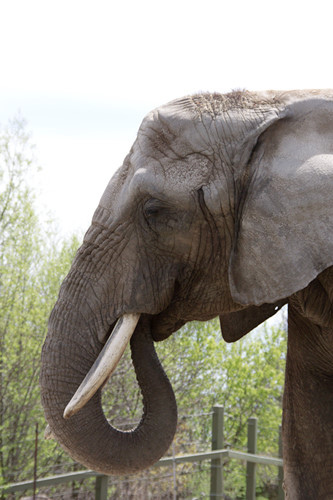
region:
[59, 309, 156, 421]
White tusk of elephant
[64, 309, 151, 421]
Grey and white tusk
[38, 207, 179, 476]
Curved trunk of elephant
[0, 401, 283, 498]
Steel rope gate in the background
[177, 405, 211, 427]
Steel rope of gate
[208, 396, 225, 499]
Green post of gate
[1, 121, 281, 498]
Green trees behind elephant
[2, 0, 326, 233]
Sky in the color of white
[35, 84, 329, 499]
Large grey elephant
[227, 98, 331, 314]
Large ear of elephant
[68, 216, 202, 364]
elephant's skin is wrinkled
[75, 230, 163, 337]
elephant's skin is wrinkled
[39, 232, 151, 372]
elephant's skin is wrinkled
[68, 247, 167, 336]
a gray, wrinkled skin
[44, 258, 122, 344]
a gray, wrinkled skin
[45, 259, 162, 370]
a gray, wrinkled skin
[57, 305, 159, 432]
long white tusk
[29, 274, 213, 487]
tusk on the side of the trunk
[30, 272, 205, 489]
trunk is curled up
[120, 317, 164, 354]
tip of the trunk is in the mouth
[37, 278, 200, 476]
lines on the trunk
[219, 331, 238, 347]
rounded tip of the ear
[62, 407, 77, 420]
tip of the tusk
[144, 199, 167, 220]
eye on the side of the head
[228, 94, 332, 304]
large ear on the side of the head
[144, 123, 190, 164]
lines on the skin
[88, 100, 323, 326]
an elephant eating a meal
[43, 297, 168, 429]
the elephant's tusk is white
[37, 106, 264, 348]
this elephant is old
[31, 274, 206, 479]
the elephant's trunk is curved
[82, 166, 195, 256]
the elephant's eyes look tired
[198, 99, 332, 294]
the ear on the elephant is big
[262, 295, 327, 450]
a part of the elephant's body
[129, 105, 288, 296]
the elephant is gray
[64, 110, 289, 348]
a big elephant eat food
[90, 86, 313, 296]
this elephant has wrinkled skin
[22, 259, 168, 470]
the trunk of a elephant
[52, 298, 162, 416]
the tusk of a elephant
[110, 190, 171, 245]
the eye of a elephant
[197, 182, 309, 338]
the ear of a elephant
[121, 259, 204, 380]
the mouth of a elephant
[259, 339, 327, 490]
the leg of a elephant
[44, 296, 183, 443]
the big white tusk of a elephant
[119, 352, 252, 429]
green leaves on trees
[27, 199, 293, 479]
the head of a elephant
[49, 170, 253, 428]
a big grey elephant